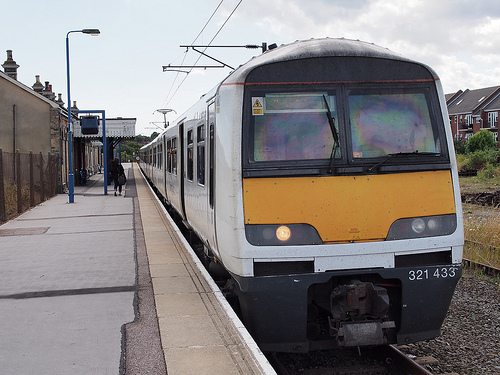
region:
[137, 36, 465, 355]
passenger train with yellow panel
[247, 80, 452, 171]
windshield of passenger train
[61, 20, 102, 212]
streetlight with blue pole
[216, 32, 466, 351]
front of passenger train with yellow panel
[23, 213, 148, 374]
concrete platform floor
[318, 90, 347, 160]
one vertical windshield wiper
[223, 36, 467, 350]
front train car with one headlight on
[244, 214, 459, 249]
headlights of train car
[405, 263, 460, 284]
serial number of train car 321 433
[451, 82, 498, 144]
two brick townhouses with grey roofs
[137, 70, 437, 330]
white yellow and black train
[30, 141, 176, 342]
concrete boarding platform at station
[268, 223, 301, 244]
round headlight on train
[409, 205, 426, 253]
round headlight on train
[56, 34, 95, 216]
blue light pole on light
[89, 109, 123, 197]
blue light pole on light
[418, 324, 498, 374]
dark gravel by tracks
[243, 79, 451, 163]
glass windshield of train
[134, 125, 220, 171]
windows on side of train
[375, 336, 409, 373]
metal rails under train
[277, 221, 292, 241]
a round train headlight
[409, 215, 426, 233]
a round train headlight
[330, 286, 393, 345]
the metal disc brakes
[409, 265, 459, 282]
white numbers on the black bumper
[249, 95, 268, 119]
a warning sticker on the windshield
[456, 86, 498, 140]
a brick apartment building nearby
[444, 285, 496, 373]
hard gray gravel next to the tracks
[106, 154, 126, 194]
a woman carrying a black bag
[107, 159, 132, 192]
a woman walking on the platform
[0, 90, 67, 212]
a mural painted on the wall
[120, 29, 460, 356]
The train is at the station.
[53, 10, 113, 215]
The light post is blue.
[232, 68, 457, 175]
The train has two windows.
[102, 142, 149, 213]
The lady is walking on the platform.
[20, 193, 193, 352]
The platform is clean.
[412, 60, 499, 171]
The houses are next to the train.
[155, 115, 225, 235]
The train doors are closed.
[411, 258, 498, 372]
Gravel is on the train tracks.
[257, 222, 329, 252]
The lights of the train are on.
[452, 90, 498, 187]
The tree is next to the houses.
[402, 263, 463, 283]
white numbers on black surface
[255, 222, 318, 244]
headlights with only one turned on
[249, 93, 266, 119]
yellow caution sign sticker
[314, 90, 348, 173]
large black windshield wiper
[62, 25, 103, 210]
blue street light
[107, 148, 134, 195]
woman walking with large bag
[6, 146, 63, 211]
fence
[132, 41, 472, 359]
white and yellow commuter train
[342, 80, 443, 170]
window that is not clean with wiper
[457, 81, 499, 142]
brick apartments